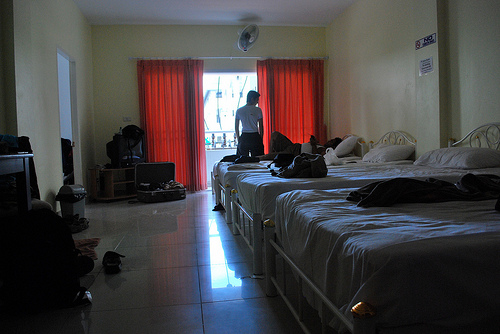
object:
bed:
[227, 120, 484, 280]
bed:
[217, 127, 418, 225]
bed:
[209, 130, 367, 211]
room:
[2, 0, 483, 330]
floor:
[56, 185, 322, 332]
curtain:
[136, 59, 202, 190]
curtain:
[258, 60, 326, 155]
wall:
[327, 1, 500, 147]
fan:
[235, 23, 259, 52]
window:
[202, 72, 257, 186]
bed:
[277, 188, 499, 333]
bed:
[235, 165, 500, 217]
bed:
[214, 160, 284, 189]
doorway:
[58, 50, 77, 188]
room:
[58, 56, 71, 138]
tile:
[119, 227, 193, 250]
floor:
[92, 190, 281, 334]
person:
[233, 90, 265, 157]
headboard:
[446, 120, 498, 151]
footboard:
[229, 186, 269, 284]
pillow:
[360, 145, 415, 164]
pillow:
[414, 148, 500, 169]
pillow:
[335, 136, 356, 156]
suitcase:
[137, 163, 185, 201]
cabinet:
[91, 164, 136, 201]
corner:
[90, 20, 94, 179]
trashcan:
[55, 184, 87, 219]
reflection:
[205, 199, 236, 289]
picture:
[419, 57, 435, 74]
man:
[240, 131, 343, 164]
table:
[1, 153, 35, 209]